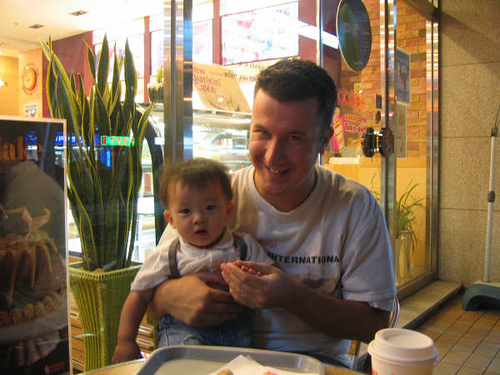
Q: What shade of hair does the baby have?
A: Brown.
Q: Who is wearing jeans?
A: The little boy.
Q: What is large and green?
A: Plant.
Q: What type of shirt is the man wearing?
A: Short sleeved.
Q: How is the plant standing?
A: In a vase.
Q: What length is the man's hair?
A: Short.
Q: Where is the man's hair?
A: On his head.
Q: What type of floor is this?
A: Tile.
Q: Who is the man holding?
A: A baby.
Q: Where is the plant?
A: Behind the man.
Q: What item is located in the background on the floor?
A: A scraper pan.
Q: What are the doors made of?
A: Glass.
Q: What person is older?
A: The man.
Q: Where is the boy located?
A: In the man's lap.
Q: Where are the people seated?
A: At a table.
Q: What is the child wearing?
A: A white shirt and overalls.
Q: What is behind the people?
A: A store.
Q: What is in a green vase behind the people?
A: A large plant.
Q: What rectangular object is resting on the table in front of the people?
A: A tray.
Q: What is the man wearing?
A: A white shirt.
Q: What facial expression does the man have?
A: A smile.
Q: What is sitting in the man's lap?
A: A baby.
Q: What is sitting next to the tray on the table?
A: A coffee cup.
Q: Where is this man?
A: Restaurant.